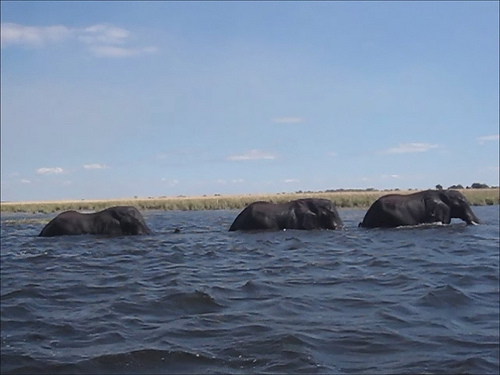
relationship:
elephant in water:
[357, 187, 480, 229] [1, 205, 498, 371]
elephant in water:
[226, 196, 341, 232] [1, 205, 498, 371]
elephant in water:
[37, 206, 179, 237] [1, 205, 498, 371]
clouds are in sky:
[3, 17, 165, 62] [3, 1, 498, 204]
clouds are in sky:
[17, 161, 114, 187] [3, 1, 498, 204]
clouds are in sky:
[210, 149, 279, 163] [3, 1, 498, 204]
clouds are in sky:
[268, 115, 304, 127] [3, 1, 498, 204]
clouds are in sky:
[366, 139, 441, 159] [3, 1, 498, 204]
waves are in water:
[19, 347, 254, 371] [1, 205, 498, 371]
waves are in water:
[155, 287, 226, 303] [1, 205, 498, 371]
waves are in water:
[412, 280, 477, 304] [1, 205, 498, 371]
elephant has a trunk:
[357, 187, 480, 229] [464, 212, 482, 227]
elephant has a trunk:
[37, 206, 179, 237] [146, 225, 180, 240]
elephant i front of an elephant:
[357, 187, 480, 229] [226, 196, 341, 232]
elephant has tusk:
[357, 187, 480, 229] [467, 221, 479, 225]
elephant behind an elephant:
[226, 196, 341, 232] [357, 187, 480, 229]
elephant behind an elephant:
[37, 206, 179, 237] [226, 196, 341, 232]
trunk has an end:
[146, 225, 180, 240] [171, 228, 183, 234]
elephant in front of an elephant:
[357, 187, 480, 229] [226, 196, 341, 232]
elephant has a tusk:
[357, 187, 480, 229] [467, 221, 479, 225]